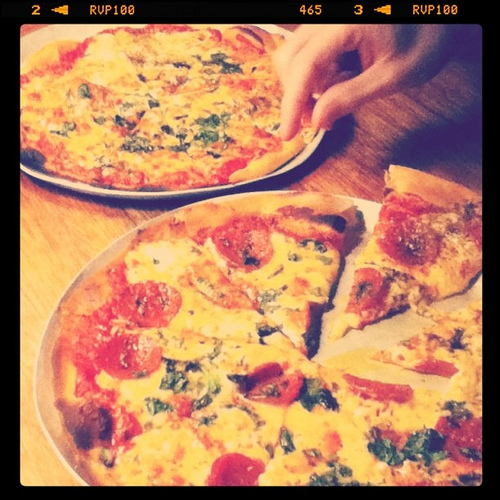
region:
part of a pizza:
[453, 291, 462, 300]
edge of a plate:
[173, 345, 179, 359]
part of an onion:
[106, 403, 116, 422]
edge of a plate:
[91, 377, 105, 403]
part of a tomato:
[318, 362, 344, 382]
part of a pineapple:
[288, 403, 323, 417]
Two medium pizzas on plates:
[18, 22, 478, 483]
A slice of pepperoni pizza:
[327, 161, 477, 336]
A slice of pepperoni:
[120, 280, 180, 325]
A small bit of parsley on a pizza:
[300, 375, 340, 410]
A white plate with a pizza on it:
[30, 187, 476, 482]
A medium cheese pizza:
[20, 23, 320, 190]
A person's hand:
[272, 23, 476, 140]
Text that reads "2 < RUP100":
[30, 3, 135, 19]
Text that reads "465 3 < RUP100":
[300, 3, 460, 18]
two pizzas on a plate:
[42, 44, 435, 359]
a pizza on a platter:
[92, 202, 476, 472]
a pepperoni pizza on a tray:
[76, 217, 470, 462]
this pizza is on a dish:
[42, 40, 353, 198]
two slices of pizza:
[192, 162, 482, 342]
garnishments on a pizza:
[152, 360, 452, 478]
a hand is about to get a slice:
[268, 32, 418, 167]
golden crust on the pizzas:
[153, 163, 354, 221]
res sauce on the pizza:
[58, 138, 246, 190]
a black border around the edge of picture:
[0, 5, 496, 490]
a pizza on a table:
[20, 20, 335, 185]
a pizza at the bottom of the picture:
[20, 165, 480, 483]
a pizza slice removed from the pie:
[331, 163, 493, 338]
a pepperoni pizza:
[90, 200, 485, 485]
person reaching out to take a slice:
[270, 25, 451, 141]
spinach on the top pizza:
[86, 50, 237, 151]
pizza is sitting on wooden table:
[20, 26, 486, 482]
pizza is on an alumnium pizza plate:
[32, 187, 496, 492]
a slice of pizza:
[330, 165, 482, 337]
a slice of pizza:
[370, 297, 480, 384]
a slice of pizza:
[311, 358, 479, 484]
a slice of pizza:
[255, 366, 407, 483]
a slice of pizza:
[88, 358, 302, 483]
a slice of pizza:
[58, 307, 303, 462]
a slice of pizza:
[63, 217, 303, 354]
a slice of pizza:
[171, 187, 356, 355]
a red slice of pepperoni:
[212, 215, 273, 265]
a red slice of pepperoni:
[378, 212, 438, 264]